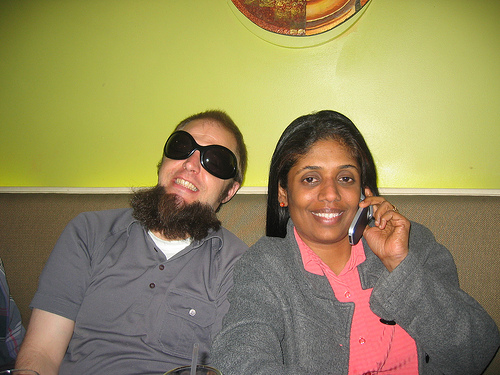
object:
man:
[31, 109, 254, 374]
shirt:
[28, 199, 249, 375]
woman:
[219, 109, 495, 375]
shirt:
[210, 212, 498, 373]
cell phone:
[346, 186, 375, 246]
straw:
[189, 340, 206, 371]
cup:
[163, 360, 224, 375]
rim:
[160, 362, 229, 374]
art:
[228, 1, 375, 37]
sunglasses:
[161, 129, 241, 186]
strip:
[0, 186, 499, 198]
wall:
[3, 3, 499, 340]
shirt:
[0, 260, 28, 365]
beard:
[127, 184, 223, 238]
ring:
[390, 202, 399, 212]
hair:
[265, 110, 382, 242]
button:
[188, 306, 197, 316]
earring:
[279, 202, 284, 208]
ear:
[277, 179, 289, 207]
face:
[157, 121, 242, 208]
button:
[343, 290, 352, 299]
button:
[358, 337, 366, 345]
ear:
[218, 178, 242, 204]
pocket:
[153, 284, 221, 356]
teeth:
[175, 178, 196, 193]